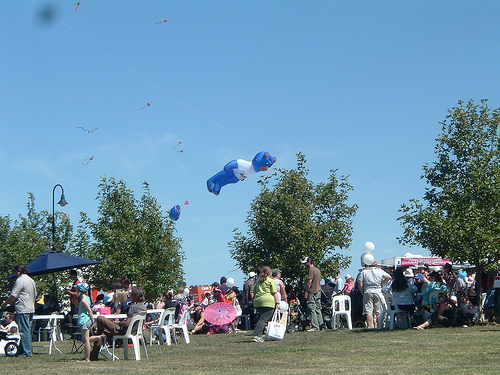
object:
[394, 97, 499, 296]
trees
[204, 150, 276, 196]
balloon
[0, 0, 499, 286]
sky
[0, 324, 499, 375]
grass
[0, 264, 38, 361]
man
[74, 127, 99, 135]
kite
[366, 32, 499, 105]
sky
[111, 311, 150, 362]
chair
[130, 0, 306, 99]
sky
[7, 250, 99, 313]
umbrella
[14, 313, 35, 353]
jeans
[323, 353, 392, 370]
lawn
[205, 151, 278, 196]
teddy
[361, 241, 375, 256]
balloons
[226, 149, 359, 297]
tree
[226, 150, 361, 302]
tree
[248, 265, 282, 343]
woman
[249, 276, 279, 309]
shirt